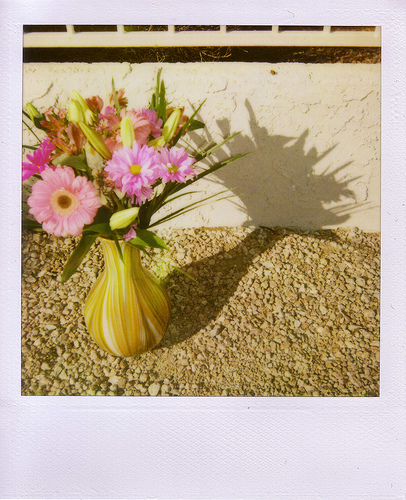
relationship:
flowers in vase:
[32, 96, 215, 234] [75, 216, 203, 358]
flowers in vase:
[30, 160, 180, 240] [63, 233, 207, 355]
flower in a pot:
[150, 144, 196, 182] [82, 229, 170, 357]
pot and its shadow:
[82, 229, 170, 357] [150, 222, 275, 352]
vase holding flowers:
[80, 227, 172, 356] [13, 66, 253, 296]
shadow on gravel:
[149, 98, 379, 352] [235, 277, 339, 374]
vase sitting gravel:
[80, 227, 172, 356] [22, 224, 380, 395]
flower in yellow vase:
[26, 162, 103, 240] [80, 235, 173, 360]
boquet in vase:
[23, 66, 250, 292] [80, 227, 172, 356]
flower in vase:
[27, 163, 103, 237] [80, 227, 172, 356]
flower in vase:
[154, 144, 201, 184] [80, 227, 172, 356]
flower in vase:
[102, 142, 161, 202] [80, 227, 172, 356]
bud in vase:
[109, 206, 141, 230] [80, 227, 172, 356]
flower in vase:
[21, 136, 56, 181] [80, 227, 172, 356]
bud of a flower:
[103, 199, 145, 235] [35, 76, 191, 266]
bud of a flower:
[78, 117, 112, 156] [103, 136, 167, 202]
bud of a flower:
[120, 116, 132, 147] [105, 145, 160, 192]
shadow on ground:
[231, 110, 335, 238] [297, 139, 327, 204]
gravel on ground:
[262, 286, 353, 371] [21, 220, 379, 403]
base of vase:
[82, 292, 169, 354] [80, 227, 172, 356]